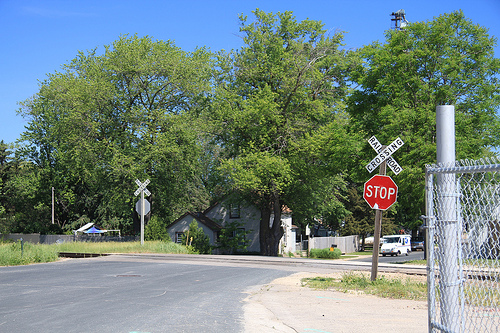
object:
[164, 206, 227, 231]
roof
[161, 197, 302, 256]
house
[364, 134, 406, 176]
sign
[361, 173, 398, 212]
stop sign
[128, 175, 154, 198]
crossing sign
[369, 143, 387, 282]
pole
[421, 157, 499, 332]
fence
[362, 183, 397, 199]
letters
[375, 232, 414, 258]
truck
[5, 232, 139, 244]
fence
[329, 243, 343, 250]
mailbox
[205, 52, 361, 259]
tree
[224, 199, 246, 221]
windows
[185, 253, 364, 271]
road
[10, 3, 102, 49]
sky